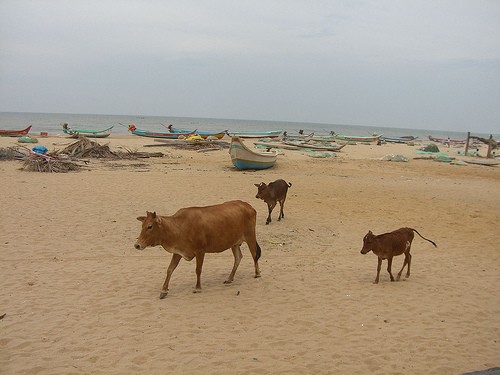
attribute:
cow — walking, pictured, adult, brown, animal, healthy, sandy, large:
[136, 199, 262, 299]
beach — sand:
[2, 133, 495, 368]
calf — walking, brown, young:
[362, 227, 438, 279]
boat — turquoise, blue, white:
[228, 133, 286, 169]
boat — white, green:
[60, 124, 114, 137]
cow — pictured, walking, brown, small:
[254, 178, 292, 224]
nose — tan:
[135, 243, 144, 250]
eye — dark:
[146, 225, 151, 230]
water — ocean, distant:
[4, 109, 495, 141]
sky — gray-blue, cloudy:
[4, 3, 499, 129]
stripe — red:
[146, 131, 174, 139]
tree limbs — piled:
[62, 140, 166, 160]